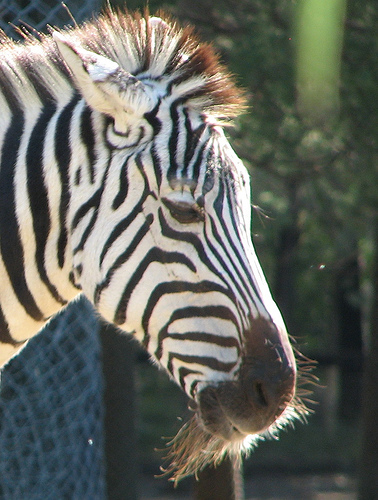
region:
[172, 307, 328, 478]
zebra's nose is brown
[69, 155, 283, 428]
a black and white stripes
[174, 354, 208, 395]
Black and white stripe of fur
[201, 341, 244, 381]
Black and white stripe of fur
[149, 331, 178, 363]
Black and white stripe of fur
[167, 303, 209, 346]
Black and white stripe of fur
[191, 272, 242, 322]
Black and white stripe of fur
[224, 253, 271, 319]
Black and white stripe of fur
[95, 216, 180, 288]
Black and white stripe of fur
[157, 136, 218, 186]
Black and white stripe of fur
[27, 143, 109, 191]
Black and white stripe of fur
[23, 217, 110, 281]
Black and white stripe of fur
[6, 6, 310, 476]
the head of a zebra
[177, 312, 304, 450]
muzzle of zebra is black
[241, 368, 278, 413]
nostril of zebra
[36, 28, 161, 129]
left ear of zebra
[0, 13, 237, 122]
black and white mane of zebra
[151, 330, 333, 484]
fine hair on muzzle of zebra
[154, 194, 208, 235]
eye of zebra is black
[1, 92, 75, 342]
wide stripes on neck of zebra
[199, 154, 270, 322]
vertical stripes on front of zebra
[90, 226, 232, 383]
thin stripes on head of zebra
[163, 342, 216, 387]
Black and white stripes on animal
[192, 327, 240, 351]
Black and white stripes on animal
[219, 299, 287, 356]
Black and white stripes on animal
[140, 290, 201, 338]
Black and white stripes on animal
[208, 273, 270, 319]
Black and white stripes on animal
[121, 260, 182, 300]
Black and white stripes on animal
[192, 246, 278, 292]
Black and white stripes on animal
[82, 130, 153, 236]
Black and white stripes on animal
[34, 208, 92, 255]
Black and white stripes on animal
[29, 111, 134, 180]
Black and white stripes on animal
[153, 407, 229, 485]
chin hairs on zebra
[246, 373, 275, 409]
zebra has large nostrils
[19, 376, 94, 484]
chain fence behind zebra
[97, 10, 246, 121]
mane is sticking straight up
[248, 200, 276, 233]
long eyelashes on zebra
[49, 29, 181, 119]
ears are back on zebra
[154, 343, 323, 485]
whiskers on face of zebra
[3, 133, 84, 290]
black and white stripes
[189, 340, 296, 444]
mouth and nose are black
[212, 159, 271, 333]
stripes on face of zebra